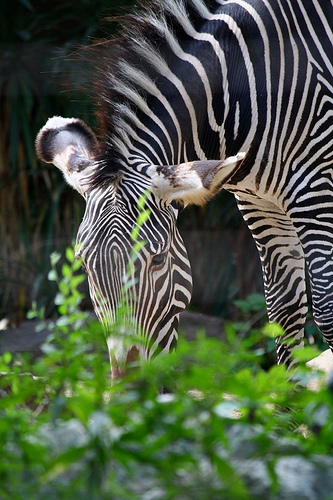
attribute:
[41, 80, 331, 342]
zebra — black and white 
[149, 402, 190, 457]
leaves — green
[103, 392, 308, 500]
branches — brown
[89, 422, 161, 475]
leaves — green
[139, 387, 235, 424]
branches — brown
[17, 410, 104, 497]
branches — brown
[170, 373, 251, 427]
leaves — green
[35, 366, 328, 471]
plants — green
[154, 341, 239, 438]
leaves — green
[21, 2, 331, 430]
zebra — eating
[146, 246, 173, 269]
eye — black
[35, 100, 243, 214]
ears — long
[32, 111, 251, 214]
ears — white , black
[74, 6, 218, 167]
mane — black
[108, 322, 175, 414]
muzzle — black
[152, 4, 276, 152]
stripes — thick 